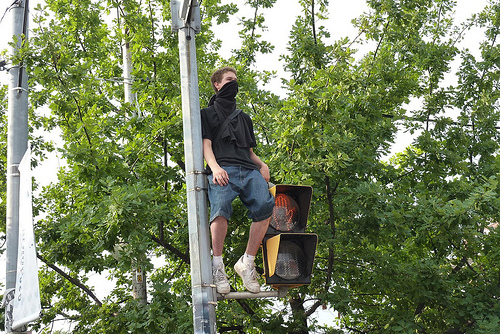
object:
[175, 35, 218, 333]
pole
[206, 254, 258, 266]
socks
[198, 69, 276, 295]
boy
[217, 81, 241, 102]
mask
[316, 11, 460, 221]
section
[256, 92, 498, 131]
power line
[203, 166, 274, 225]
shorts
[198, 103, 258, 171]
shirt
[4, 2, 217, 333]
steel poles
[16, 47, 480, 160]
wires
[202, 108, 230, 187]
arm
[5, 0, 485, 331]
trees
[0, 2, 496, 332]
background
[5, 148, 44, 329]
advertisement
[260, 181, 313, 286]
holder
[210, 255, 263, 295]
shoes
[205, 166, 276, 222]
jeans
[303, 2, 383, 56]
sky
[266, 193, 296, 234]
hand